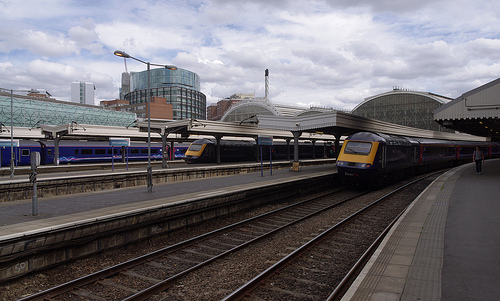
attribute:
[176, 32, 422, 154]
building — white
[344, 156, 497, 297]
platform — paved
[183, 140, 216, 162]
left — yellow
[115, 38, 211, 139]
building — tall, green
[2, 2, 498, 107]
sky — blue, cloudy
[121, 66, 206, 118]
building — glass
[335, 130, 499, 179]
train — yellow, black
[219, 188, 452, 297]
tracks — empty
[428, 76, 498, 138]
awning — white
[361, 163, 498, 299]
platform — paved